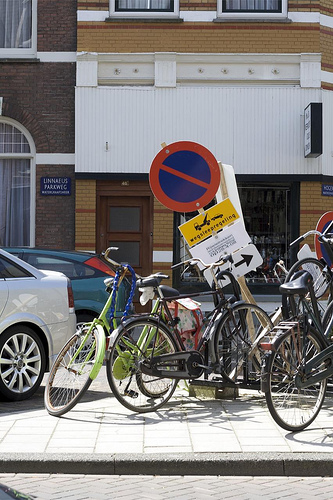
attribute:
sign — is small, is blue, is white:
[321, 183, 331, 198]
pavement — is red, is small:
[2, 414, 332, 494]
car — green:
[3, 243, 132, 354]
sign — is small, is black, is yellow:
[170, 202, 243, 248]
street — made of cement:
[6, 421, 331, 450]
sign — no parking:
[145, 143, 226, 221]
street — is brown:
[3, 290, 331, 497]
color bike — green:
[32, 246, 116, 415]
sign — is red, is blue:
[140, 129, 231, 226]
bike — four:
[43, 247, 178, 414]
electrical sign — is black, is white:
[301, 102, 324, 160]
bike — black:
[102, 252, 271, 415]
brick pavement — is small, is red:
[1, 470, 331, 499]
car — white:
[0, 245, 77, 401]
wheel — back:
[109, 325, 176, 409]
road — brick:
[0, 472, 332, 499]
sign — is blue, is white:
[40, 177, 71, 196]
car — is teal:
[10, 225, 124, 415]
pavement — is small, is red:
[6, 470, 329, 499]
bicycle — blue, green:
[45, 243, 187, 415]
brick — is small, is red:
[223, 36, 238, 44]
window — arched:
[0, 114, 35, 247]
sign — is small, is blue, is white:
[39, 176, 71, 195]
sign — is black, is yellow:
[178, 198, 242, 246]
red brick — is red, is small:
[0, 471, 332, 499]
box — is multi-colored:
[166, 295, 205, 359]